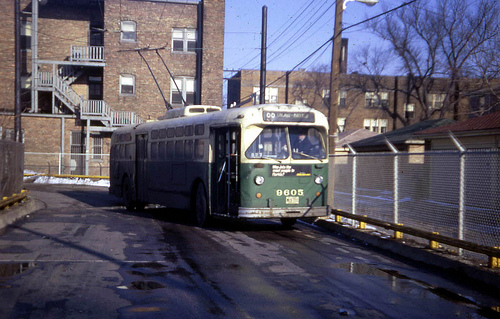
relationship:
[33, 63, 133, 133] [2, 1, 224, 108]
staircase attached to building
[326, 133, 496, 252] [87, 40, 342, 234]
fence next to bus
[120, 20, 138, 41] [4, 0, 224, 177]
window on building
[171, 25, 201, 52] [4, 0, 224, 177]
window on building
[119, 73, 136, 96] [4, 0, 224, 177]
window on building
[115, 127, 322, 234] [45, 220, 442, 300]
bus on road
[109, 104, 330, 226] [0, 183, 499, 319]
bus on ground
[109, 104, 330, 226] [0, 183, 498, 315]
bus on road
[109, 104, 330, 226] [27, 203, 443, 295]
bus on street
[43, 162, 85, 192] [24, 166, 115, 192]
snow on road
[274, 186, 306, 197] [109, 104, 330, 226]
number are on bus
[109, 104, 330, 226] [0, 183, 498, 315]
bus driving on road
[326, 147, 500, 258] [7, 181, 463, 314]
fence next to road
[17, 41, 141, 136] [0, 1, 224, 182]
metal stairway for apartment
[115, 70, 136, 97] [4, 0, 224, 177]
window on building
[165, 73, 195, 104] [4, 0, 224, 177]
window on building